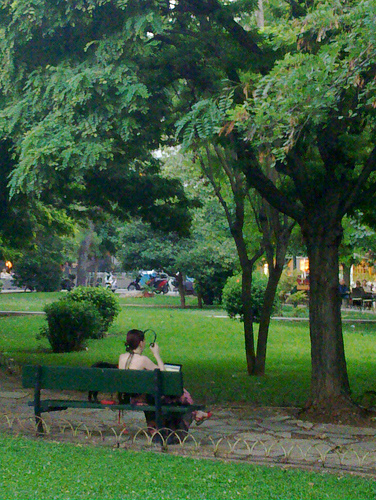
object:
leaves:
[217, 82, 237, 113]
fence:
[6, 408, 374, 471]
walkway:
[2, 381, 371, 481]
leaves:
[34, 202, 78, 238]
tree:
[0, 54, 200, 248]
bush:
[36, 298, 101, 353]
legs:
[72, 388, 110, 414]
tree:
[289, 0, 375, 429]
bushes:
[43, 284, 121, 352]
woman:
[116, 328, 213, 445]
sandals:
[190, 409, 213, 425]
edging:
[2, 412, 374, 465]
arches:
[0, 412, 373, 465]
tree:
[118, 227, 192, 310]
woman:
[117, 308, 198, 441]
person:
[354, 279, 365, 296]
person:
[339, 278, 350, 302]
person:
[360, 278, 372, 291]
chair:
[350, 287, 362, 306]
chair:
[363, 298, 373, 308]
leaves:
[0, 1, 165, 202]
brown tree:
[0, 0, 376, 421]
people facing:
[352, 276, 375, 300]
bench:
[20, 353, 205, 414]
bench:
[13, 359, 211, 444]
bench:
[19, 365, 220, 412]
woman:
[117, 327, 211, 426]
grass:
[179, 307, 222, 358]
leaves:
[214, 61, 314, 142]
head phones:
[141, 326, 157, 347]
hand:
[148, 341, 160, 353]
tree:
[184, 63, 307, 377]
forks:
[236, 252, 285, 375]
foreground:
[2, 332, 347, 496]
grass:
[6, 439, 373, 494]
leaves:
[0, 0, 373, 231]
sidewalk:
[1, 376, 374, 476]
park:
[2, 283, 375, 499]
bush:
[218, 265, 282, 323]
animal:
[82, 356, 138, 407]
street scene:
[1, 256, 364, 317]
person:
[336, 278, 346, 297]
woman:
[114, 324, 219, 436]